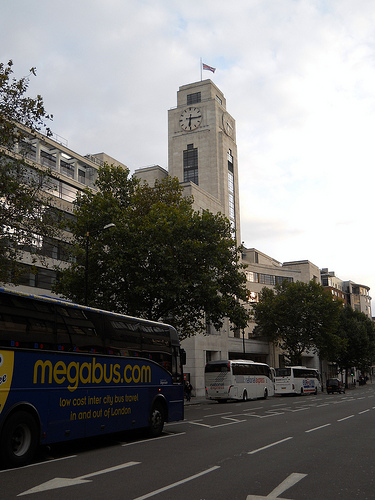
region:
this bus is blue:
[0, 274, 199, 470]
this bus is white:
[200, 353, 283, 408]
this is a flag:
[195, 58, 216, 81]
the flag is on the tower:
[193, 56, 223, 85]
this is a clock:
[174, 104, 207, 137]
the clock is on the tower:
[176, 106, 209, 136]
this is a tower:
[160, 75, 246, 324]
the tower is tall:
[159, 77, 239, 259]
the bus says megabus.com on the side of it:
[27, 357, 155, 393]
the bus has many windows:
[0, 289, 175, 378]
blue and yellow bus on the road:
[0, 284, 193, 465]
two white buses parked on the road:
[200, 357, 322, 408]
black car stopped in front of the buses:
[325, 376, 346, 397]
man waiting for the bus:
[179, 377, 195, 401]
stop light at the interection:
[346, 365, 358, 389]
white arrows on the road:
[18, 458, 320, 498]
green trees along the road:
[0, 57, 373, 398]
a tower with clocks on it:
[161, 79, 244, 234]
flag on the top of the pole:
[193, 55, 219, 85]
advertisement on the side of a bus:
[4, 352, 154, 427]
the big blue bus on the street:
[4, 286, 190, 451]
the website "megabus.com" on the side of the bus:
[31, 355, 154, 393]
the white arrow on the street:
[9, 456, 135, 498]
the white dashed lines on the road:
[167, 411, 369, 471]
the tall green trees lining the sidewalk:
[7, 163, 374, 392]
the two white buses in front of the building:
[200, 348, 321, 410]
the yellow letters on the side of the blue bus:
[29, 358, 153, 421]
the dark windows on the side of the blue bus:
[2, 292, 169, 385]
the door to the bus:
[169, 340, 183, 422]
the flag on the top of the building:
[200, 56, 218, 80]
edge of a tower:
[199, 127, 229, 178]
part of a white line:
[274, 456, 295, 487]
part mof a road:
[299, 437, 324, 458]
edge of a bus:
[217, 360, 249, 393]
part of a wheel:
[237, 383, 251, 399]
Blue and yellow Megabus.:
[0, 277, 195, 468]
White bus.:
[200, 352, 277, 406]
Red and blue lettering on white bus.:
[240, 372, 267, 391]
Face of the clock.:
[173, 104, 209, 132]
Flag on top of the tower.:
[195, 55, 220, 79]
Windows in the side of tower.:
[178, 141, 203, 189]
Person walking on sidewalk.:
[184, 377, 193, 404]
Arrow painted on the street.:
[8, 448, 145, 497]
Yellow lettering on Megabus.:
[31, 350, 167, 431]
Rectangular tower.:
[163, 54, 243, 283]